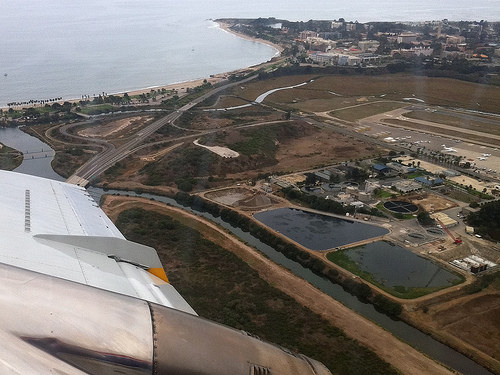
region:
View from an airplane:
[2, 1, 497, 372]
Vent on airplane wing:
[241, 361, 267, 374]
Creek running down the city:
[89, 174, 498, 374]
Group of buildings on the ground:
[300, 129, 498, 282]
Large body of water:
[0, 1, 498, 111]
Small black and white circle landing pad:
[378, 183, 421, 223]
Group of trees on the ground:
[398, 128, 498, 214]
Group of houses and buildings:
[258, 10, 498, 77]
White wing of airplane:
[4, 163, 204, 324]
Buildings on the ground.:
[281, 124, 449, 262]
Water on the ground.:
[146, 132, 387, 359]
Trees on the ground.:
[162, 79, 401, 257]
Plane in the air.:
[3, 154, 180, 349]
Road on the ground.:
[57, 92, 242, 181]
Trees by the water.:
[169, 187, 396, 323]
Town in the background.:
[308, 18, 465, 88]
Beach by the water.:
[59, 65, 237, 102]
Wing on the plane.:
[61, 170, 198, 374]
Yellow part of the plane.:
[121, 242, 162, 288]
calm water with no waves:
[4, 5, 207, 74]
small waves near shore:
[28, 90, 78, 97]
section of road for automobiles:
[83, 161, 100, 171]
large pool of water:
[265, 207, 365, 247]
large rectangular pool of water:
[337, 241, 457, 292]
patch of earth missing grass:
[197, 274, 257, 316]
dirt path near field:
[311, 295, 329, 312]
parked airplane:
[441, 142, 461, 155]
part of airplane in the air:
[0, 170, 195, 373]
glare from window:
[407, 45, 437, 138]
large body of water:
[3, 3, 499, 92]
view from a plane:
[1, 2, 499, 372]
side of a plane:
[1, 158, 328, 374]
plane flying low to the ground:
[0, 91, 499, 373]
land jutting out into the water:
[207, 13, 292, 47]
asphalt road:
[66, 48, 280, 182]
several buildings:
[289, 21, 494, 69]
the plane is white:
[1, 166, 275, 374]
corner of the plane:
[74, 176, 92, 194]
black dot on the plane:
[77, 219, 85, 229]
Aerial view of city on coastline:
[53, 18, 498, 374]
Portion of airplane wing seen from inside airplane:
[1, 168, 331, 373]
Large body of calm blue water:
[1, 0, 498, 108]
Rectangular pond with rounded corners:
[323, 237, 466, 302]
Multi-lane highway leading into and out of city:
[64, 64, 292, 187]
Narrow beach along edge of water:
[1, 17, 288, 114]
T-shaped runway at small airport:
[358, 106, 499, 147]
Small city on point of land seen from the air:
[250, 15, 497, 70]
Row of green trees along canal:
[173, 190, 403, 319]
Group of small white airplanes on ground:
[438, 142, 491, 162]